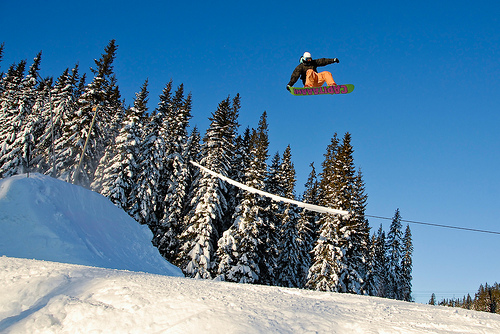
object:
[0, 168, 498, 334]
snow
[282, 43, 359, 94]
man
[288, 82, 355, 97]
drsnowboard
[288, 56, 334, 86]
black coat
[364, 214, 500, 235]
black wire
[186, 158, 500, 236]
powerline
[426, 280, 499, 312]
tree group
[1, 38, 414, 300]
tree group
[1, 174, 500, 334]
white snow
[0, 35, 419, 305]
tree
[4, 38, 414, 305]
trees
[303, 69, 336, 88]
pants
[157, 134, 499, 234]
wire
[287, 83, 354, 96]
snowboard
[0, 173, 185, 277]
snow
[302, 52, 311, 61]
hat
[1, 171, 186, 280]
snowbank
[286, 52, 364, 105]
snowboarder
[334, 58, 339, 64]
glove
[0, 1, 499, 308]
sky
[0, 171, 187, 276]
hill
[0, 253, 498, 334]
snow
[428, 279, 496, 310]
trees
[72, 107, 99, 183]
pole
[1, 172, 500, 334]
mountain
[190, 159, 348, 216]
ice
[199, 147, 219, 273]
snow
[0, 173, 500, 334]
ground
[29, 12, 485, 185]
air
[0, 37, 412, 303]
grove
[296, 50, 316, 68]
head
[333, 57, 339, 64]
hand